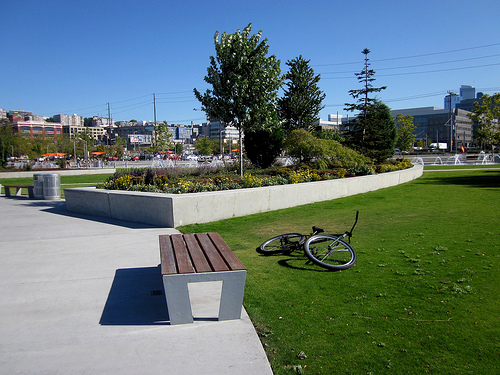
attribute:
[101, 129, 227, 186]
cars — parked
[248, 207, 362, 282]
bicycle — black 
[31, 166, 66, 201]
cans — large, steel, trash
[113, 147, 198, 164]
cars — parked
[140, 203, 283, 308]
bench — brown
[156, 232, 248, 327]
bench — stone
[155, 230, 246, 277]
seat — wooden, slat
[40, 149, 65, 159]
umbrella — orange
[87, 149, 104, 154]
umbrella — orange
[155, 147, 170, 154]
umbrella — orange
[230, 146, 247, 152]
umbrella — orange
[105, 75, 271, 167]
poles — grey, large, electricity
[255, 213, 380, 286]
bicycle — lying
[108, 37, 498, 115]
electric wires — gray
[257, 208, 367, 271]
bike — lying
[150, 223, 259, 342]
bench — empty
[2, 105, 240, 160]
buildings — many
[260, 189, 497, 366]
grass — green, short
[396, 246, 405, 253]
clover — green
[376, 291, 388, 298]
clover — green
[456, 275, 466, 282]
clover — green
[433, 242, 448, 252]
clover — green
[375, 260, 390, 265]
clover — green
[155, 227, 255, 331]
bench — wood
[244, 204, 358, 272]
bike — lying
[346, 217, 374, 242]
handlebar — black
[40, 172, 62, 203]
garbage can — silver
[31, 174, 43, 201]
garbage can — silver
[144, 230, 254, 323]
bench — brown, white